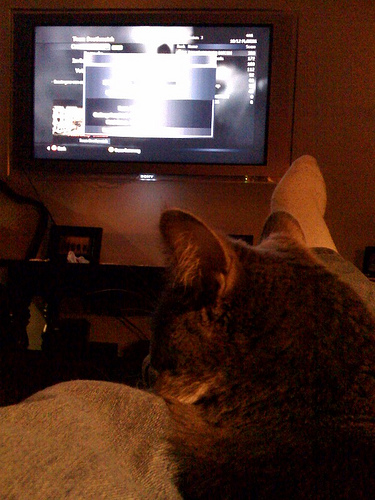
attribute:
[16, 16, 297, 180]
television — on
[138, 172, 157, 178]
logo — white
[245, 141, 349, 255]
socks — white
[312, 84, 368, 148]
wall — brown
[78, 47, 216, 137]
box —  black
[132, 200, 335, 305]
furry ears — two pointy furry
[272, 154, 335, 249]
sock — white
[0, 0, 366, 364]
wall — white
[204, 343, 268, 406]
neck — light brown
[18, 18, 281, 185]
television — on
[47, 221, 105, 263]
frame — small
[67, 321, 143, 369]
items — below 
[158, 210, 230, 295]
animal's ear — pointed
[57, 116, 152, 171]
writing — white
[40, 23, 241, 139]
tv — under 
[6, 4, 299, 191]
tv — on, bright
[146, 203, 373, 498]
animal — back 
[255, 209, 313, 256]
ear — brown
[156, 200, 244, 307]
ear — brown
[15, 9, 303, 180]
frame — grey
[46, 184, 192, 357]
table — black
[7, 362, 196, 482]
lap — persons 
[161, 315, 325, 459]
camera — facing 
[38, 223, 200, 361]
table — dark wooden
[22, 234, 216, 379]
table — below 